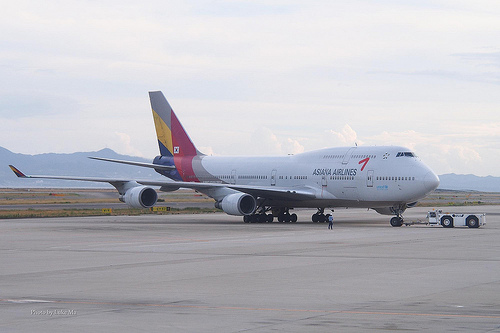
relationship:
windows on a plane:
[385, 171, 405, 191] [9, 85, 492, 285]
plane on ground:
[9, 85, 492, 285] [259, 217, 357, 247]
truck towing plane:
[424, 203, 488, 233] [9, 85, 492, 285]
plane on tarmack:
[9, 85, 492, 285] [17, 210, 498, 328]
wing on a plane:
[4, 164, 324, 216] [5, 88, 443, 229]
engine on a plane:
[124, 185, 159, 209] [9, 85, 492, 285]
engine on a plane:
[116, 185, 159, 209] [9, 85, 492, 285]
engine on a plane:
[116, 185, 159, 209] [83, 80, 444, 232]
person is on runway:
[324, 210, 336, 233] [298, 231, 383, 267]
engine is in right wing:
[111, 180, 161, 212] [4, 157, 316, 217]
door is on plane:
[361, 164, 386, 192] [9, 77, 499, 241]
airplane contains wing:
[0, 83, 473, 243] [4, 148, 323, 208]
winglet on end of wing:
[4, 160, 34, 181] [3, 165, 253, 192]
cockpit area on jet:
[388, 148, 417, 163] [33, 102, 446, 209]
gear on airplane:
[305, 209, 338, 225] [5, 90, 496, 240]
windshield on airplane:
[394, 148, 415, 161] [5, 90, 496, 240]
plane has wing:
[9, 85, 492, 285] [2, 157, 279, 192]